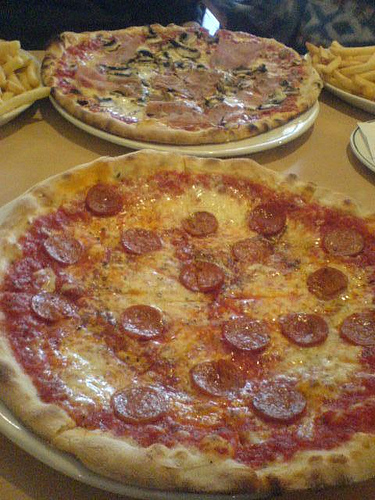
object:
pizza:
[0, 148, 374, 498]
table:
[1, 37, 374, 499]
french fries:
[330, 34, 373, 106]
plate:
[2, 102, 40, 125]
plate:
[0, 419, 245, 500]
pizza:
[43, 14, 325, 145]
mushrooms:
[174, 42, 202, 60]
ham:
[209, 40, 261, 68]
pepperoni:
[247, 201, 287, 239]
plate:
[345, 115, 374, 171]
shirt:
[211, 5, 375, 48]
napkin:
[355, 118, 375, 161]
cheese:
[164, 191, 227, 210]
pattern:
[304, 8, 366, 37]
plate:
[314, 76, 374, 112]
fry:
[1, 85, 54, 114]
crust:
[38, 38, 61, 84]